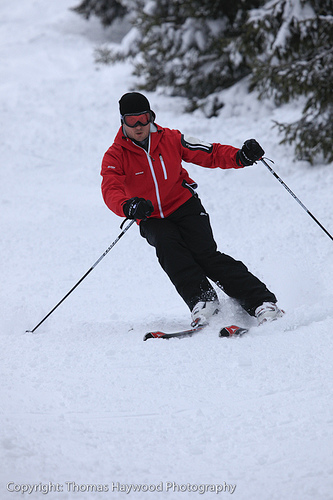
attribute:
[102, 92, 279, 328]
man — focused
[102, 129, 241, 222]
jacket — red, black, white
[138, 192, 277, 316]
pants — black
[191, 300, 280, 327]
boots — white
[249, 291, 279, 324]
boot — white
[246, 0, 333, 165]
tree — green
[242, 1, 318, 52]
snow — white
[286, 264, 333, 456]
snow — white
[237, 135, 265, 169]
glove — black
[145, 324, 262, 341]
skies — red, black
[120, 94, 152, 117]
cap — black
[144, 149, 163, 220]
zipper — white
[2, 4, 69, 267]
snow — white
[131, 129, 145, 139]
mouth — open